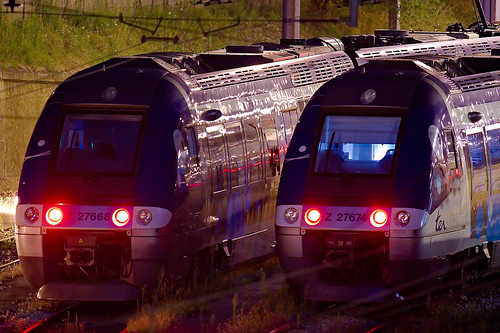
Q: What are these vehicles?
A: Trains.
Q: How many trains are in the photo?
A: 2.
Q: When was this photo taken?
A: During the evening.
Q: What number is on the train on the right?
A: 27674.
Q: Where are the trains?
A: On the tracks.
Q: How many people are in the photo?
A: None.